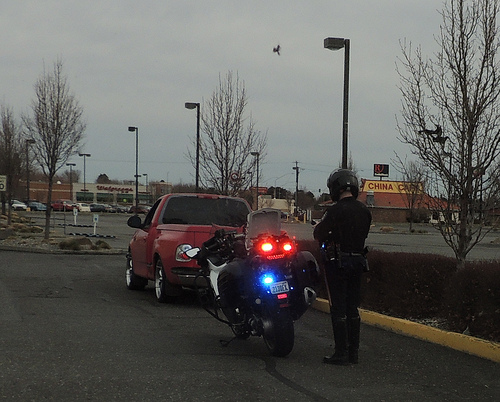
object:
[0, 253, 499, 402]
street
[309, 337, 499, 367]
curb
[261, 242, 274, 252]
light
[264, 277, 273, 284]
light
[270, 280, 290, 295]
license plate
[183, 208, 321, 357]
motorcycle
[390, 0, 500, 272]
tree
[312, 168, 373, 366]
police officer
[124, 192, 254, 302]
truck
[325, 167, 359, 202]
helmet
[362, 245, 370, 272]
gun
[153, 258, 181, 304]
rim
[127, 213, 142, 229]
mirror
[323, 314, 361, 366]
boots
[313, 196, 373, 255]
shirt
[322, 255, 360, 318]
pants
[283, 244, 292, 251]
light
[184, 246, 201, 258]
mirror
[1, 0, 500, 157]
sky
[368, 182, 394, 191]
china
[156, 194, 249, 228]
rear windshield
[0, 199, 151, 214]
cars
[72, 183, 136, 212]
walgreens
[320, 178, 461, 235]
restaurant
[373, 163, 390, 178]
sign